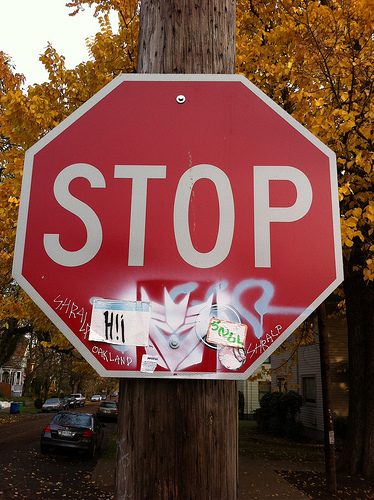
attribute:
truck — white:
[68, 390, 88, 405]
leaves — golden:
[354, 207, 363, 216]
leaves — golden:
[353, 191, 365, 204]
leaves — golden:
[355, 229, 359, 244]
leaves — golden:
[355, 209, 364, 219]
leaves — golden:
[346, 216, 356, 227]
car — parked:
[37, 406, 109, 462]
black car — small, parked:
[41, 409, 105, 462]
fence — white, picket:
[0, 399, 12, 408]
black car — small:
[42, 408, 103, 452]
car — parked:
[88, 392, 101, 402]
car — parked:
[41, 414, 97, 458]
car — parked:
[32, 391, 60, 418]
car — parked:
[64, 392, 86, 408]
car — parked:
[41, 408, 100, 466]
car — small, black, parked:
[40, 408, 99, 452]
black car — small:
[37, 410, 108, 460]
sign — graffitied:
[8, 68, 346, 376]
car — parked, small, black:
[38, 389, 110, 467]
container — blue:
[6, 398, 24, 414]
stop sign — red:
[21, 42, 352, 381]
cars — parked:
[0, 384, 139, 468]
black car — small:
[37, 410, 105, 456]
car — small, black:
[39, 408, 112, 463]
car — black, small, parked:
[36, 400, 92, 462]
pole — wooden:
[317, 303, 338, 495]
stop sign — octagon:
[9, 63, 351, 385]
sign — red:
[79, 68, 326, 328]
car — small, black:
[44, 403, 98, 462]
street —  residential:
[2, 395, 104, 496]